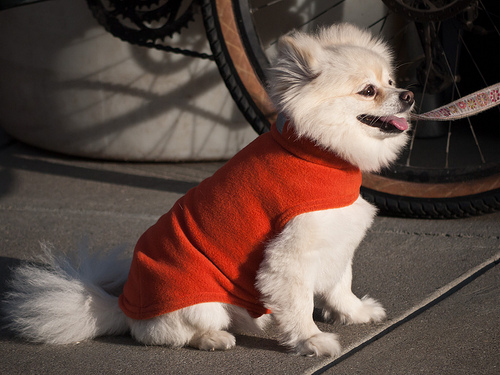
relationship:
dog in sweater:
[13, 26, 417, 351] [124, 130, 357, 315]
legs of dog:
[266, 227, 380, 358] [13, 26, 417, 351]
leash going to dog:
[403, 87, 499, 137] [13, 26, 417, 351]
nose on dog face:
[396, 90, 415, 106] [271, 36, 408, 164]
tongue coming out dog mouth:
[380, 112, 409, 134] [353, 103, 413, 150]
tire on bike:
[201, 12, 498, 195] [100, 7, 499, 215]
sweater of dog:
[124, 130, 357, 315] [13, 26, 417, 351]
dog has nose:
[13, 26, 417, 351] [396, 90, 415, 106]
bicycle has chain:
[100, 7, 499, 215] [101, 7, 216, 70]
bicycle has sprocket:
[100, 7, 499, 215] [89, 0, 204, 42]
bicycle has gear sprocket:
[100, 7, 499, 215] [89, 0, 204, 42]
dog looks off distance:
[13, 26, 417, 351] [7, 20, 499, 334]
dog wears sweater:
[13, 26, 417, 351] [124, 130, 357, 315]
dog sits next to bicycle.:
[13, 26, 417, 351] [100, 7, 499, 215]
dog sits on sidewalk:
[13, 26, 417, 351] [5, 159, 484, 373]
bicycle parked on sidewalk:
[100, 7, 499, 215] [5, 159, 484, 373]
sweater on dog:
[124, 130, 357, 315] [13, 26, 417, 351]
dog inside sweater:
[13, 26, 417, 351] [124, 130, 357, 315]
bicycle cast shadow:
[100, 7, 499, 215] [46, 16, 232, 189]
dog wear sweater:
[13, 26, 417, 351] [124, 130, 357, 315]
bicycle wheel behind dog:
[201, 12, 498, 195] [13, 26, 417, 351]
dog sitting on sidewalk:
[13, 26, 417, 351] [5, 159, 484, 373]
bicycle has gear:
[100, 7, 499, 215] [89, 0, 204, 42]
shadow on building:
[46, 16, 232, 189] [7, 15, 376, 155]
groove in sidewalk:
[371, 248, 498, 339] [5, 159, 484, 373]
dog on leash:
[13, 26, 417, 351] [403, 87, 499, 137]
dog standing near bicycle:
[13, 26, 417, 351] [100, 7, 499, 215]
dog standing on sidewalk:
[13, 26, 417, 351] [5, 159, 484, 373]